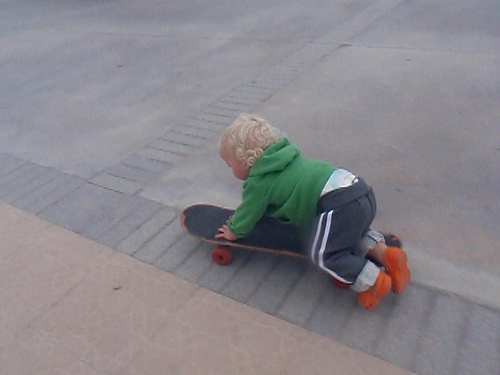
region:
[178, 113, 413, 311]
a toddler on a skateboard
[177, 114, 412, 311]
a small male child on a skateboard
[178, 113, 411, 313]
a baby boy on a wooden skateboard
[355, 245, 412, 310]
orange shoes on the toddler's feet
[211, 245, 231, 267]
an orange wheel on the skateboard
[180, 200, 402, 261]
a black wooden skateboard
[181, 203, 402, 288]
a skateboard with orange wheels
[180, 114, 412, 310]
a toddler on the hands and and knees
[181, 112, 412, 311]
a baby on the knees and hands on a skateboard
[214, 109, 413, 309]
a toddler in a green hoodie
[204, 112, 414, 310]
baby on the skateboard.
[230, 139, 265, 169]
Curls in the hair.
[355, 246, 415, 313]
Orange shoes on the feet.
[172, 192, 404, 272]
black skateboard on the ground.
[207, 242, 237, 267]
Red wheel on skateboard.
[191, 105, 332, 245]
green sweatshirt on the baby.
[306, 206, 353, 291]
White stripes on the pants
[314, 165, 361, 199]
Diaper on the baby.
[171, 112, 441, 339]
This is a child sliding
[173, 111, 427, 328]
This is a child sliding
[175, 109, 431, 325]
This is a child sliding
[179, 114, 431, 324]
This is a child sliding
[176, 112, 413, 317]
This is a child sliding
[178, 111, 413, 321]
This is a child sliding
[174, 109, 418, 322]
This is a child sliding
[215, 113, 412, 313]
little blonde child on a skateboard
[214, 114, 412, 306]
little boy wearing diapers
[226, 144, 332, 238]
green jacket on the little boy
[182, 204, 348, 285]
black skateboard under the boy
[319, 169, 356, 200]
white diaper on the little boy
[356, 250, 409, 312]
orange shoes on the little boy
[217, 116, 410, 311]
little boy with curly blonde hair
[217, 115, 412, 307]
little boy in a green coat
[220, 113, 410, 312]
little boy in orange shoes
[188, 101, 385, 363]
a child on a skateboard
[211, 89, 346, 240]
a child with blonde hair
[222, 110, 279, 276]
a child wearing a hoodie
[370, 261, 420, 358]
a child wearing a shoe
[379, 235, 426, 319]
a child wearing a shoe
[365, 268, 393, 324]
an orang eshoe on child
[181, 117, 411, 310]
baby is on a skateboard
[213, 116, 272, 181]
baby has blonde hair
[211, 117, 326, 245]
baby is wearing a hoodie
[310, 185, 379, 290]
baby is wearing pants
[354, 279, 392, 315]
baby is wearing shoe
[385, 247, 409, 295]
baby is wearing shoe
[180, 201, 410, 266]
skateboard is black and brown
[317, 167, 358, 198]
baby has a diaper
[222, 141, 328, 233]
hoodie is color green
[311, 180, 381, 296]
pants are black and white